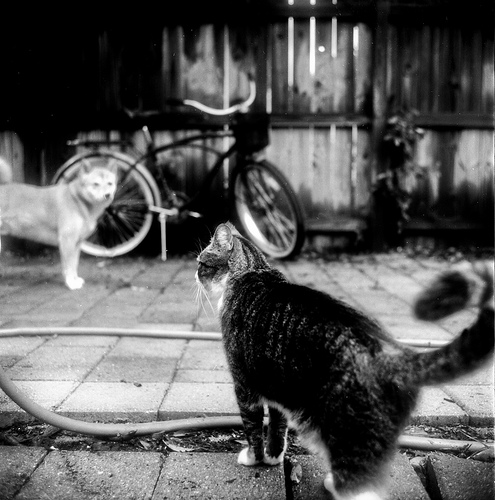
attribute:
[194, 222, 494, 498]
cat — looking away, focused, grey, white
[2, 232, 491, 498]
patio — paver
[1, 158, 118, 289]
dog — white, huskie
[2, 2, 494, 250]
fence — wooden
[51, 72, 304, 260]
bike — old style, parked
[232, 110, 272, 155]
basket — small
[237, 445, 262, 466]
paw — white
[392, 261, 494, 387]
tail — dark, curled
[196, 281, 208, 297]
chin — white